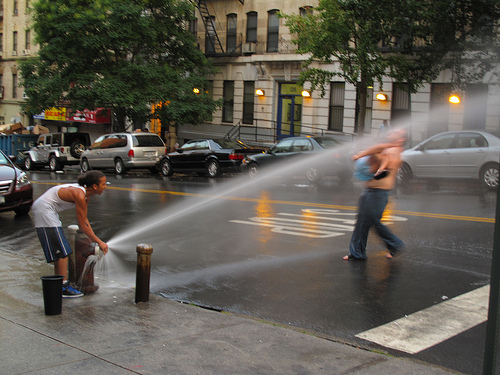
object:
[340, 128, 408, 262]
person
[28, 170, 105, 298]
person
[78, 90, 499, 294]
water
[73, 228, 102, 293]
hydrant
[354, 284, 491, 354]
line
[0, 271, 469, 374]
sidewalk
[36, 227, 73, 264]
shorts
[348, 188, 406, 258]
pants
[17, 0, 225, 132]
tree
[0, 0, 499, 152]
building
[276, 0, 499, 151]
tree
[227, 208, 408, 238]
stop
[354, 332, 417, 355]
edge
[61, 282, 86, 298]
sneakers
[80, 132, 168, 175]
car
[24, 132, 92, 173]
car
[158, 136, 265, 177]
car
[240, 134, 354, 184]
car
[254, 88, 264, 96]
light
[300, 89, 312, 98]
light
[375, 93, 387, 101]
light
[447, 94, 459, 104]
light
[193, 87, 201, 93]
light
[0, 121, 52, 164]
dumpster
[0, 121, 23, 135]
boxes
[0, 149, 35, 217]
cars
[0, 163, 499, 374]
row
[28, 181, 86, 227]
vest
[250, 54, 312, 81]
awning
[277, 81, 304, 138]
door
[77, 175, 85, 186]
ponytail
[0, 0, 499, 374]
scene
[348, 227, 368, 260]
part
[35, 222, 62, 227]
edge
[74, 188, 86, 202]
shoulder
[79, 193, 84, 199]
part